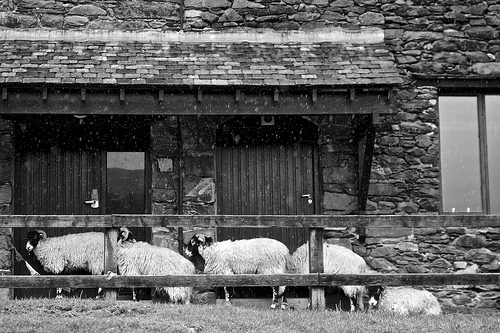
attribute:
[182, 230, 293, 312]
sheep — black, white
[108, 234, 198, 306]
sheep — white, black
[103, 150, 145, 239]
window — small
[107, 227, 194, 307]
sheep — white, black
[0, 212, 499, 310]
fence — wooden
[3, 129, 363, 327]
sheep — white, black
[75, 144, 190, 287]
door — wooden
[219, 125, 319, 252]
door — wooden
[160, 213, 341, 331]
sheep — white, black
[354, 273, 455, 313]
sheep — black, white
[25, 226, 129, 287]
sheep — black, white